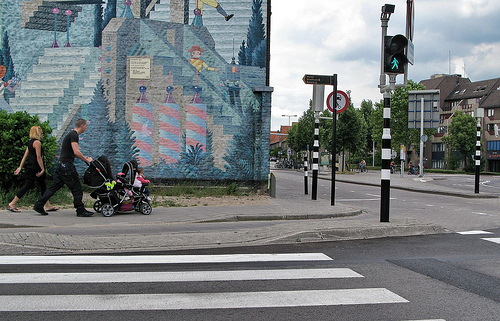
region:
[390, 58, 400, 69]
The green walking person on the cross walk light.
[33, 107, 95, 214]
The man pushing the stroller.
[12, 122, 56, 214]
The woman walking behind the man pushing the stroller.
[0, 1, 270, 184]
The mural on the wall.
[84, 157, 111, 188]
The hood on the back of the stroller.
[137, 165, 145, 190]
The child sitting in the front of the stroller.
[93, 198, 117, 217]
The back wheels of the stroller.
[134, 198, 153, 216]
The front wheels of the stroller.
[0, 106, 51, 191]
The bush to the left of the woman.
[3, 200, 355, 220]
The sidewalk the people are walking on.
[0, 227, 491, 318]
White crosswalk in street.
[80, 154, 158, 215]
Black double baby stroller.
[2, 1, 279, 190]
Mural on side of building.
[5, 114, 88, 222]
Couple going for a walk.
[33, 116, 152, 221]
Man pushing baby stroller.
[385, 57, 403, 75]
Green crossing sign.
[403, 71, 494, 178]
Gray and tan apartment buildings.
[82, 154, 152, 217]
Child riding in stroller.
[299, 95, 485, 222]
Black and white street poles.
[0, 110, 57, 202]
Green bush beside woman.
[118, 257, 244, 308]
A pedestrian crossing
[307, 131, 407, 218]
Poles in the photo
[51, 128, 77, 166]
Black t-shirt in the photo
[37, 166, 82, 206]
Black jeans in the photo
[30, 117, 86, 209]
A man in the photo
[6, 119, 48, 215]
A woman in the photo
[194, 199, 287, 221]
A side walk in the photo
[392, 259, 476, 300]
Road with tarmac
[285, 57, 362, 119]
Road signs in the photo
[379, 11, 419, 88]
A traffic light on the road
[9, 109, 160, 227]
woman and man walking with stroller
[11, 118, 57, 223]
blonde woman in black clothes walking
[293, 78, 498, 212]
black and white poles at the side of the street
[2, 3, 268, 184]
mural on the side of a building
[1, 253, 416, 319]
white stripes in the street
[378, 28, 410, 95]
street sign showing walk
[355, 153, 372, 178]
person on bicycle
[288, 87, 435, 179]
trees alongside the street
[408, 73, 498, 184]
building across the street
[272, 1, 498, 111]
overcast sky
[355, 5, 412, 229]
this is a pole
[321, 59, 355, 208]
this is a pole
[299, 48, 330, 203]
this is a pole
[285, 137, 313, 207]
this is a pole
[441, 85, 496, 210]
this is a pole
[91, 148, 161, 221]
a child in a pram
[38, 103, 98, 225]
this is a person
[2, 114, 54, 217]
this is a person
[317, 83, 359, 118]
this is a sign